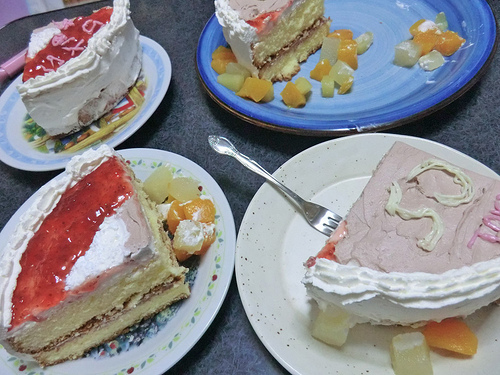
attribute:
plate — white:
[236, 128, 499, 372]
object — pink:
[0, 46, 25, 70]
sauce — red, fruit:
[17, 174, 115, 267]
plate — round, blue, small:
[68, 145, 196, 340]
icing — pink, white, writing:
[355, 149, 472, 299]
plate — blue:
[220, 25, 408, 108]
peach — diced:
[243, 59, 366, 102]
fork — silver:
[216, 128, 346, 240]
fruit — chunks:
[225, 54, 425, 125]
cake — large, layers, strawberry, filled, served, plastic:
[57, 156, 205, 294]